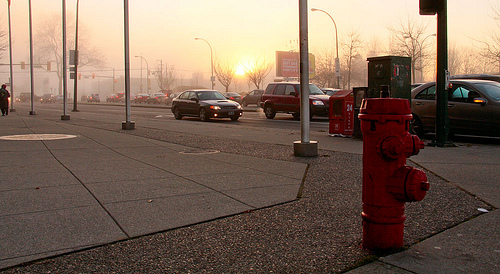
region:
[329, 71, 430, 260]
the red fire hydrant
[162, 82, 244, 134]
the compact ccar with the lights on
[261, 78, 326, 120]
the red suv in the far lane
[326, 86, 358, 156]
the newspaper box by the road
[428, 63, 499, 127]
car parked by the sidewalk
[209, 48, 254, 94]
the sunrise in the background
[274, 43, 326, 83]
the billboard advertisment in the back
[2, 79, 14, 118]
man walking on the side walk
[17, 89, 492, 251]
the entire paved sidewalk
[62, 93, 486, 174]
the street the cars are driving on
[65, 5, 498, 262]
The cars are in the city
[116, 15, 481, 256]
The cars are carrying people home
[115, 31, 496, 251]
The cars are driven by their owners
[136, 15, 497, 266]
The cars are using their headlights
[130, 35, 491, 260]
The people are driving very carefully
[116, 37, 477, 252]
The people are driving at sundown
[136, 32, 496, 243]
The people are obeying traffic laws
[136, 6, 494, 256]
The drivers are going to work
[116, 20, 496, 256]
The drivers are stopped for a red light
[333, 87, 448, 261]
A red fire hydrant is on a sidewalk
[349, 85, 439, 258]
The fire hydrant is red.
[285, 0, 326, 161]
The pole is gray.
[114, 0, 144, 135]
The pole is gray.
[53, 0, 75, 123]
The pole is gray.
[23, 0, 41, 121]
The pole is gray.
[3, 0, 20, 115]
The pole is straight.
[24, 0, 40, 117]
The pole is straight.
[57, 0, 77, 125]
The pole is straight.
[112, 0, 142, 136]
The pole is straight.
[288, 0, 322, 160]
The pole is straight.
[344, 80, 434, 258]
fire hydrant on sidewalk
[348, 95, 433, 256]
fire hydrant is red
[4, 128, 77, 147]
manhole cover in middle of sidewalk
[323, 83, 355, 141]
newspaper stand on edge of sidewalk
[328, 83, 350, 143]
newspaper stand is red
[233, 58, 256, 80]
sun is peeking through the fog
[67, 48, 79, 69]
sign attached to pole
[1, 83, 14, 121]
man standing on sidewalk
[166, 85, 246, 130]
black car with headlights on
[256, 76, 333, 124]
red vehicle riding on the road